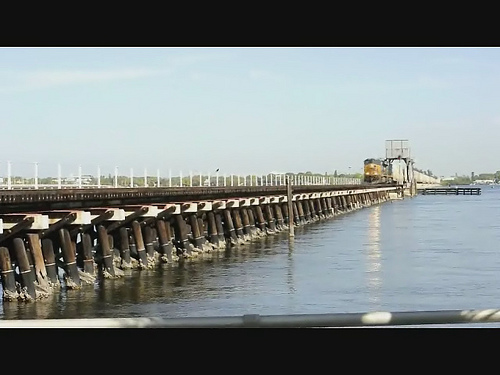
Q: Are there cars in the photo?
A: No, there are no cars.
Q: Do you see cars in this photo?
A: No, there are no cars.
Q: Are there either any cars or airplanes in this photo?
A: No, there are no cars or airplanes.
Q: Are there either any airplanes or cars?
A: No, there are no cars or airplanes.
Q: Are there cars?
A: No, there are no cars.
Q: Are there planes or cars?
A: No, there are no cars or planes.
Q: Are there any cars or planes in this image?
A: No, there are no cars or planes.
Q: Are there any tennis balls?
A: No, there are no tennis balls.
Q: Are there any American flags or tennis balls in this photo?
A: No, there are no tennis balls or American flags.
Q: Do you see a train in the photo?
A: Yes, there is a train.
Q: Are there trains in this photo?
A: Yes, there is a train.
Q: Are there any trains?
A: Yes, there is a train.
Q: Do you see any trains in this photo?
A: Yes, there is a train.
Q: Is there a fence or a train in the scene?
A: Yes, there is a train.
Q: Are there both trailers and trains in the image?
A: No, there is a train but no trailers.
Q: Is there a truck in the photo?
A: No, there are no trucks.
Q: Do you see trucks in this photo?
A: No, there are no trucks.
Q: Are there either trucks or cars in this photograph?
A: No, there are no trucks or cars.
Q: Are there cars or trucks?
A: No, there are no trucks or cars.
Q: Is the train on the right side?
A: Yes, the train is on the right of the image.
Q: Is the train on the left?
A: No, the train is on the right of the image.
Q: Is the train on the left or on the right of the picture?
A: The train is on the right of the image.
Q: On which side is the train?
A: The train is on the right of the image.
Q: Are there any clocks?
A: No, there are no clocks.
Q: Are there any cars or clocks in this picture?
A: No, there are no clocks or cars.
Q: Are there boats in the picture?
A: No, there are no boats.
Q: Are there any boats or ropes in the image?
A: No, there are no boats or ropes.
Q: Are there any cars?
A: No, there are no cars.